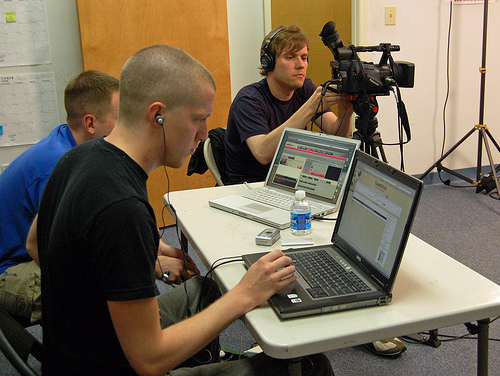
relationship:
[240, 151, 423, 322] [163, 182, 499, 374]
laptop on table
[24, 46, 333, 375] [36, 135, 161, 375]
guy wearing tshirt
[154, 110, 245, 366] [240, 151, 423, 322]
earphones attached to laptop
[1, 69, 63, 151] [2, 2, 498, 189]
calendar on wall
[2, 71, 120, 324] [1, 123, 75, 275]
man wearing tshirt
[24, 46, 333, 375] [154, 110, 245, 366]
guy wearing earphones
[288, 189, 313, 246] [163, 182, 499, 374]
bottle on table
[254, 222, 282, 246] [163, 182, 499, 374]
cell phone on table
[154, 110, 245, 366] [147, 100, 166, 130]
earphones in ear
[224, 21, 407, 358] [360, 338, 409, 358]
person wearing sneaker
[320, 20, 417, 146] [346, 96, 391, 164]
camera on tripod